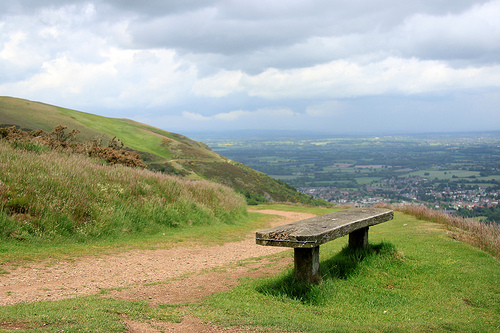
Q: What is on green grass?
A: Wooden bench.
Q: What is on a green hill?
A: Dirt road.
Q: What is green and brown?
A: Hillside.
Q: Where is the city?
A: In background.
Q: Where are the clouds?
A: In sky.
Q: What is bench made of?
A: Stone.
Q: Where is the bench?
A: Hillside.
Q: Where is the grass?
A: Hillside.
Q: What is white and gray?
A: Cloud.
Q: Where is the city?
A: Below hillside.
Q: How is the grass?
A: Dry.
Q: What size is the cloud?
A: Large.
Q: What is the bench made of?
A: Wood.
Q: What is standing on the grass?
A: A bench.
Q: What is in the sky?
A: Clouds.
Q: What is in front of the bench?
A: A dirt path.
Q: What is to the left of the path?
A: A hill.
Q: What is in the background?
A: The valley.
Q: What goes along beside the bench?
A: A walking path.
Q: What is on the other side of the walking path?
A: Tall grass on a hill.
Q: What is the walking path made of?
A: Dirt.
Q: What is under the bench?
A: A shadow.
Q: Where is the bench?
A: In grass.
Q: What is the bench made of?
A: Wood.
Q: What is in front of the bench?
A: Dirt path.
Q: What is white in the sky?
A: Clouds.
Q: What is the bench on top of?
A: A hill.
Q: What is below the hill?
A: City.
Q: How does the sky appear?
A: Cloudy.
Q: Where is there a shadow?
A: Under bench.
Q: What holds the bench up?
A: Two legs.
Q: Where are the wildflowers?
A: In grass.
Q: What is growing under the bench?
A: Grass.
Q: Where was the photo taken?
A: Overlooking a valley.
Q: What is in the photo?
A: A bench.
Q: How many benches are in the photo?
A: One.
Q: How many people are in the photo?
A: None.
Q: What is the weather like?
A: Cloudy.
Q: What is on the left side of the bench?
A: A path.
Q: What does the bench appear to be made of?
A: Stone.